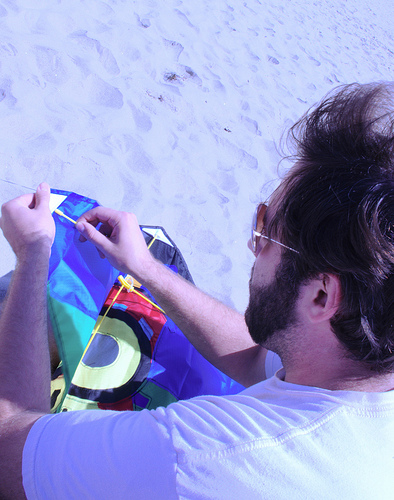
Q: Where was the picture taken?
A: On a beach.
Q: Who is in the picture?
A: A man.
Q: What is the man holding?
A: A kite.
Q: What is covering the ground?
A: Sand.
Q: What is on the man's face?
A: Sunglasses.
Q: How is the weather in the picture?
A: Sunny.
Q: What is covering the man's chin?
A: A beard.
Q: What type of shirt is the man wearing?
A: A t-shirt.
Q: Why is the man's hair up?
A: The wind is blowing.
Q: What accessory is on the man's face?
A: Sunglasses.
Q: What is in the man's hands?
A: Kite.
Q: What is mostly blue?
A: Kite.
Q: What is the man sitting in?
A: Sand.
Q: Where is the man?
A: Beach.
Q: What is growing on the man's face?
A: Beard.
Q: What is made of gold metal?
A: Sunglasses.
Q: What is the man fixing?
A: Kite.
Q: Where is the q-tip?
A: In the man's hand.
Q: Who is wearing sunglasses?
A: The man.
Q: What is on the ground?
A: Sand.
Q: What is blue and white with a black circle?
A: Kite.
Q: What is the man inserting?
A: A piece.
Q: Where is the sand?
A: On the beach.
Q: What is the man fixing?
A: A kite.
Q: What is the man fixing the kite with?
A: Q-tip.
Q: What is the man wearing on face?
A: Glasses.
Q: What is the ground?
A: Sand.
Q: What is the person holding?
A: Kite.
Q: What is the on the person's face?
A: Sunglasses.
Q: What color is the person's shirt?
A: White.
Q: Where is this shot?
A: Beach.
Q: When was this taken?
A: Daytime.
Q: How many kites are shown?
A: 1.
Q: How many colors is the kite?
A: 5.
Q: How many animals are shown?
A: 0.